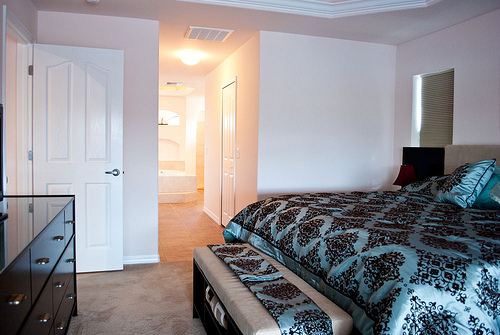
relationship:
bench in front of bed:
[180, 240, 292, 329] [306, 154, 495, 287]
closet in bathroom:
[210, 78, 286, 192] [158, 117, 205, 195]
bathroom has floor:
[158, 117, 205, 195] [168, 209, 206, 238]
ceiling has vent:
[165, 10, 240, 107] [179, 19, 240, 50]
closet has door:
[210, 78, 286, 192] [208, 82, 248, 201]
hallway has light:
[169, 82, 221, 209] [171, 47, 204, 70]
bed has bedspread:
[306, 154, 495, 287] [364, 260, 456, 312]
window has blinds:
[415, 80, 456, 123] [430, 114, 456, 126]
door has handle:
[35, 44, 129, 237] [91, 163, 117, 180]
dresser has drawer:
[37, 194, 102, 295] [49, 218, 80, 266]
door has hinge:
[35, 44, 129, 237] [17, 149, 45, 169]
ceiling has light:
[165, 10, 240, 107] [171, 47, 204, 70]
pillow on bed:
[440, 163, 493, 210] [306, 154, 495, 287]